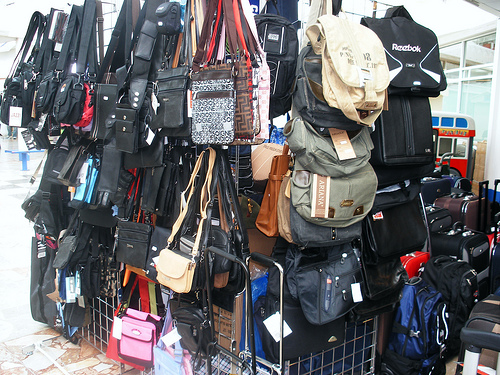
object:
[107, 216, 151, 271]
bags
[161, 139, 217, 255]
strap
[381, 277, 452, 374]
backpack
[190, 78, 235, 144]
design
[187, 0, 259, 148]
purse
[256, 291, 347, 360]
displat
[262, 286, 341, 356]
bags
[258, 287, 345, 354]
messenger bags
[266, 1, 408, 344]
row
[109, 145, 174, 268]
purse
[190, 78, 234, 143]
letter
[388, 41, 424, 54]
brand name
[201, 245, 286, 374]
cart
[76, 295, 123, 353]
wire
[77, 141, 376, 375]
rack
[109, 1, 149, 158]
purses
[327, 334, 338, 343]
logo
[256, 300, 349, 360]
bag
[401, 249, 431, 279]
suitcase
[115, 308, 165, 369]
bag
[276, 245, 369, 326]
bag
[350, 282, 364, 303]
tag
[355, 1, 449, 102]
bag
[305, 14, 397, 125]
backpack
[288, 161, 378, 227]
print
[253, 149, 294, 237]
bag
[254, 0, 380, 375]
rack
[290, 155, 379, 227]
bag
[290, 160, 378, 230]
bag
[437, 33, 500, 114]
rack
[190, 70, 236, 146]
bag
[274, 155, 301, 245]
bag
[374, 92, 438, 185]
bag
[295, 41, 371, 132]
bag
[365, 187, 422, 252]
bag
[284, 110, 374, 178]
bag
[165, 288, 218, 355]
bag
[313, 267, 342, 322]
stripe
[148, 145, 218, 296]
bag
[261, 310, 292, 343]
tag